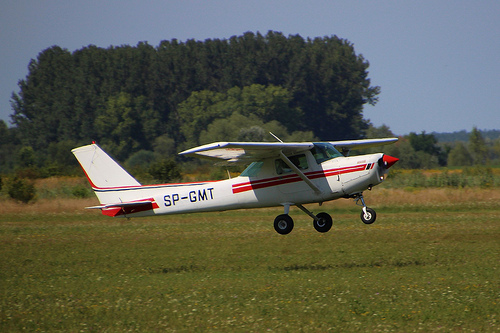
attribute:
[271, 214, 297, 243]
wheel — retractable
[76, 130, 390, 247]
plane — name, white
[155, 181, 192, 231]
letter — black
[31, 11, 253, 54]
sky — blue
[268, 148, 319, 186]
window — small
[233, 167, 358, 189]
line — red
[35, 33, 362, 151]
trees — green, large, pine, tall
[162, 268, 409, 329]
flower — white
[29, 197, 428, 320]
grass — green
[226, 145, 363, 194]
stripe — red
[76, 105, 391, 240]
airplane — white, private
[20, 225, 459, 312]
field — grassy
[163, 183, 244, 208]
writing — black